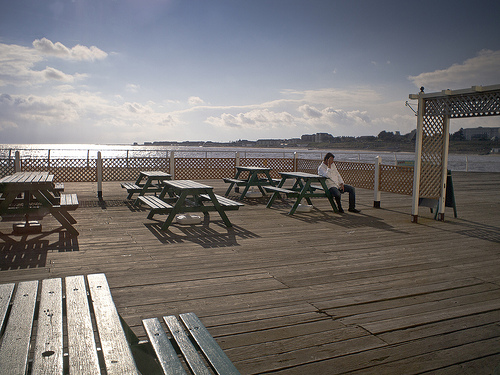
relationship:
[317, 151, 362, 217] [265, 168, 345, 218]
person sitting at a picnic table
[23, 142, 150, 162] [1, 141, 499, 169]
reflection on water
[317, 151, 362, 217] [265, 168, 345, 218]
person at picnic table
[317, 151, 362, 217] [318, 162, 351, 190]
person wearing a shirt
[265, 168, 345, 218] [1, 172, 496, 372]
picnic table on deck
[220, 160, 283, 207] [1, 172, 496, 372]
picnic table on deck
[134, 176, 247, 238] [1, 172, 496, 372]
picnic table on deck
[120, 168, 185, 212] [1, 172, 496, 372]
picnic table on deck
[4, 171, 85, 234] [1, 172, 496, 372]
picnic table on deck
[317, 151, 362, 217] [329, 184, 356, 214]
person wearing blue jeans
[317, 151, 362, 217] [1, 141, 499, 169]
person sitting near water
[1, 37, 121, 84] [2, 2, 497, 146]
cloud in sky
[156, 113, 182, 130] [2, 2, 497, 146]
cloud in sky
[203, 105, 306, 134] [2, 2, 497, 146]
cloud in sky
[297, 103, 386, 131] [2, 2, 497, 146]
cloud in sky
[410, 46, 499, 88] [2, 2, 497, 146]
cloud in sky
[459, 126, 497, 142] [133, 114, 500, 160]
building in distance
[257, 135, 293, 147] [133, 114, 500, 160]
building in distance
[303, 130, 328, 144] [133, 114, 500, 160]
building in distance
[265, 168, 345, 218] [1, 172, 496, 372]
picnic table outside on deck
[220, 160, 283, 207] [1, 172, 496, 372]
picnic table outside on deck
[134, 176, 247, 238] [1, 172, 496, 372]
picnic table outside on deck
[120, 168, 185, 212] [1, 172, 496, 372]
picnic table outside on deck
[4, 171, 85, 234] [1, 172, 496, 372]
picnic table outside on deck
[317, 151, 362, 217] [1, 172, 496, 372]
person sitting on deck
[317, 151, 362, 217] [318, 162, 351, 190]
person has shirt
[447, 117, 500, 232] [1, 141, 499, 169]
entrance to water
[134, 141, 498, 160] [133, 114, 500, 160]
land in distance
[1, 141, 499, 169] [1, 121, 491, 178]
water in background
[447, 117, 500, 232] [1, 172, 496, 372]
entrance near deck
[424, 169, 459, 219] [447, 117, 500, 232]
sign in front of entrance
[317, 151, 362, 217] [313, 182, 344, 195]
person sitting on a bench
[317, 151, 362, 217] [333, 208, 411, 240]
person has shadow